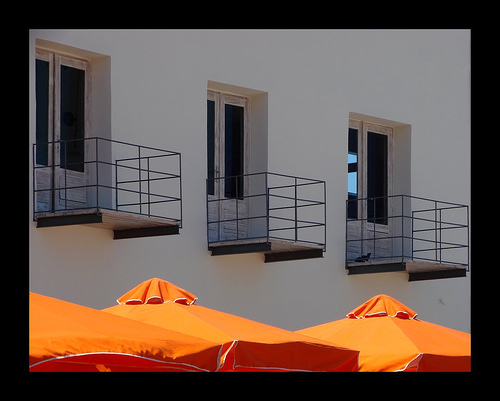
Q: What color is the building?
A: White.